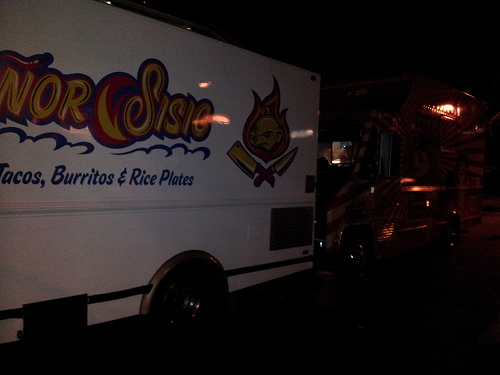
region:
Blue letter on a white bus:
[186, 165, 198, 191]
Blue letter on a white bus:
[182, 170, 192, 194]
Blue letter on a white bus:
[175, 163, 187, 192]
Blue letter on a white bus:
[170, 176, 181, 187]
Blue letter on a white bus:
[163, 163, 177, 190]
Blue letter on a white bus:
[129, 163, 156, 195]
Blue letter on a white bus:
[50, 158, 116, 195]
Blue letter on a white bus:
[0, 155, 52, 197]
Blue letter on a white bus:
[0, 158, 210, 204]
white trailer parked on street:
[1, 0, 326, 338]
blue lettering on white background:
[2, 153, 199, 196]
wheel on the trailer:
[144, 268, 231, 353]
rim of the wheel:
[172, 283, 211, 333]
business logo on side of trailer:
[5, 40, 318, 192]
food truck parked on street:
[320, 100, 470, 275]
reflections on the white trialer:
[62, 62, 312, 146]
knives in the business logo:
[225, 142, 297, 192]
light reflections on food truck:
[375, 89, 475, 219]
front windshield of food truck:
[325, 132, 351, 172]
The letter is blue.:
[0, 169, 15, 186]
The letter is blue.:
[10, 165, 25, 185]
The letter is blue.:
[19, 168, 34, 185]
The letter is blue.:
[30, 165, 42, 187]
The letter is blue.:
[45, 156, 67, 186]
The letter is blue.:
[60, 170, 75, 188]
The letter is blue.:
[124, 163, 141, 188]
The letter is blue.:
[153, 163, 172, 188]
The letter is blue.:
[93, 170, 108, 187]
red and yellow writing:
[0, 50, 220, 156]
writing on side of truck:
[0, 58, 252, 154]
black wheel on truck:
[147, 268, 230, 350]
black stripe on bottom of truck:
[238, 258, 308, 282]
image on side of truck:
[218, 82, 314, 197]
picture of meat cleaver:
[220, 146, 260, 173]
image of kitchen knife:
[243, 150, 303, 200]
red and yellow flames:
[240, 66, 300, 158]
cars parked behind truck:
[314, 171, 456, 276]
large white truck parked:
[0, 0, 337, 344]